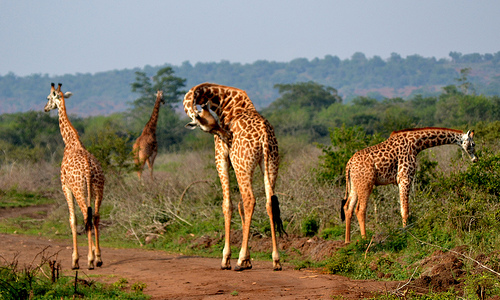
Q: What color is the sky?
A: Blue.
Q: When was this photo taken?
A: Outside, during the daytime.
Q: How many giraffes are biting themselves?
A: One.